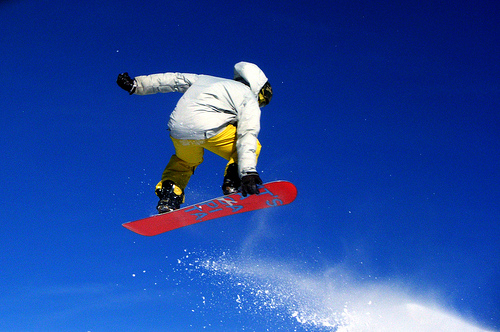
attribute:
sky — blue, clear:
[2, 3, 491, 330]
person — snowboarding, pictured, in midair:
[116, 57, 272, 199]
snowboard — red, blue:
[118, 178, 296, 238]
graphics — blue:
[185, 179, 281, 217]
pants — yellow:
[157, 126, 264, 191]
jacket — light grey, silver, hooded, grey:
[131, 60, 272, 174]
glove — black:
[236, 172, 268, 198]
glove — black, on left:
[114, 71, 139, 94]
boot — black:
[224, 160, 241, 196]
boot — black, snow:
[151, 178, 182, 213]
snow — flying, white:
[175, 242, 478, 330]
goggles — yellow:
[263, 83, 271, 102]